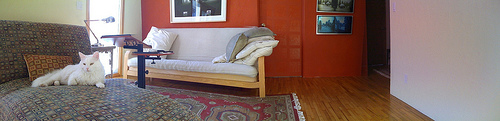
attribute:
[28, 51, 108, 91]
cat — white, laying on bed, sitting, adult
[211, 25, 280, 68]
pillows — stacked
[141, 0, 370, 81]
wall — orange, bright orange, painted orange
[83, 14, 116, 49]
lamp — metal, adjustable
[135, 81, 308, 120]
rug — multi-colored, persian, red, on floor, fringed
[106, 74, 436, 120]
floor — wood, hardwood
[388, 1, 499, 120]
wall — white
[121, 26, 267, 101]
futon — wooden, white, white colored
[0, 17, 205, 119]
bed — small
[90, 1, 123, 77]
window — large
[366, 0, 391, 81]
doorway — on the right, entrance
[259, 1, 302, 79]
door — orange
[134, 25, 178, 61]
pillow — white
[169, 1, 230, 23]
picture — large, rectangular, framed